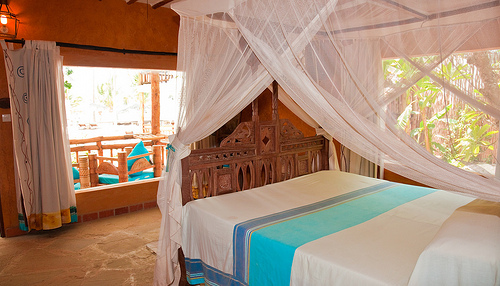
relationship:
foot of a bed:
[179, 118, 329, 201] [170, 118, 499, 285]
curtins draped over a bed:
[172, 1, 498, 161] [163, 117, 499, 282]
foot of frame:
[179, 118, 329, 206] [181, 257, 211, 284]